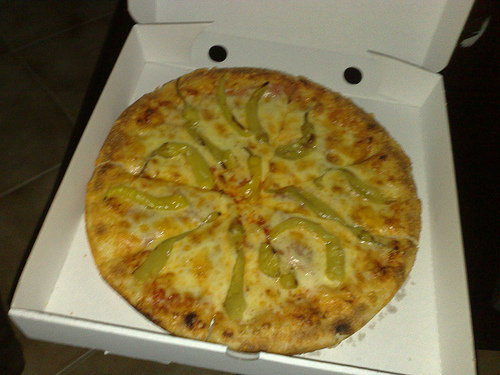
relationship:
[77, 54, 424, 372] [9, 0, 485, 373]
pizza inside box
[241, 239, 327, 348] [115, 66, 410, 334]
part of the pizza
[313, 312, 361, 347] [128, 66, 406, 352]
edge of a pizza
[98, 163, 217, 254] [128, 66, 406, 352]
part of a pizza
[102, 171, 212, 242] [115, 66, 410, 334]
part of a pizza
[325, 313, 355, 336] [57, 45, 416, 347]
edge of a pizza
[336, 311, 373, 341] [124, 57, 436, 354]
edge of a pizza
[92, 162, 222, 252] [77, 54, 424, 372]
part of a pizza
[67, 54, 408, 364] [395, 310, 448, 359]
food in a box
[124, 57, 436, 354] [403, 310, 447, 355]
pizza in a box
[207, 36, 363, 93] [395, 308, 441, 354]
holes in a box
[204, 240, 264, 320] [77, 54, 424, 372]
peppers on top pizza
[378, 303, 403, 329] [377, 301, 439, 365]
grease on  a box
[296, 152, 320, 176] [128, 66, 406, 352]
cheese on  a pizza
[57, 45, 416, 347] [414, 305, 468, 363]
pizza in  a box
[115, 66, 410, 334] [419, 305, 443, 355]
pizza sitting in box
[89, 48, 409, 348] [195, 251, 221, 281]
pizza with cheese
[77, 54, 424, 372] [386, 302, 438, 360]
pizza in a box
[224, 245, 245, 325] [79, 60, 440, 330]
peppers on a pizza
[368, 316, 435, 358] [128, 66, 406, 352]
box with pizza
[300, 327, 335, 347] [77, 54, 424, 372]
crust on pizza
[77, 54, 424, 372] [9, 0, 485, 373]
pizza in box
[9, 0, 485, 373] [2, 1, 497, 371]
box on floor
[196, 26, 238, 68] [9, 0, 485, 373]
hole in box